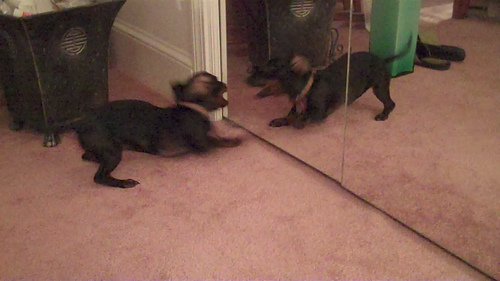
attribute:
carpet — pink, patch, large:
[3, 65, 499, 280]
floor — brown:
[3, 18, 496, 280]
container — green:
[367, 0, 421, 80]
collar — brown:
[178, 98, 213, 126]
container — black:
[0, 0, 130, 150]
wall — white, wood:
[98, 0, 224, 128]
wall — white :
[123, 16, 207, 76]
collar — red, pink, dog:
[173, 95, 215, 119]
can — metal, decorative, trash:
[2, 0, 127, 148]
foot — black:
[39, 131, 63, 149]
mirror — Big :
[235, 31, 492, 122]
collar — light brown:
[173, 98, 212, 118]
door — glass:
[221, 0, 353, 198]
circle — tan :
[52, 17, 96, 62]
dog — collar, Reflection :
[41, 72, 251, 187]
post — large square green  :
[371, 16, 418, 71]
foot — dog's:
[101, 169, 140, 199]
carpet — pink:
[80, 191, 260, 279]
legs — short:
[79, 135, 244, 195]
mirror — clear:
[356, 137, 441, 189]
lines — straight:
[284, 156, 466, 265]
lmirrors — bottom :
[342, 57, 451, 216]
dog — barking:
[88, 70, 255, 174]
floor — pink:
[150, 236, 230, 278]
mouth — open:
[216, 85, 234, 106]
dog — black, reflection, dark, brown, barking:
[68, 70, 250, 192]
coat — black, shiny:
[65, 103, 190, 136]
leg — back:
[80, 129, 139, 190]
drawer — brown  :
[41, 22, 111, 86]